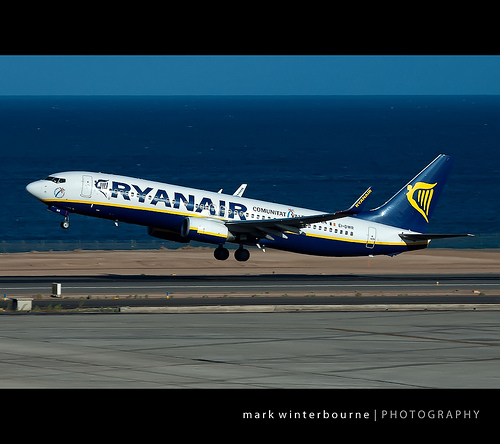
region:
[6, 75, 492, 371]
An airport scene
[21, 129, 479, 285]
This is a passenger jet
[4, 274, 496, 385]
This is a runway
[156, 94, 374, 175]
The ocean is in the background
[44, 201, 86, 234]
The plane's front landing gear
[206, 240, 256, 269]
These are the rear landing gears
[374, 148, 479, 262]
The jet's tail section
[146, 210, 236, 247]
The jet has two engines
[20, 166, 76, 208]
This is the plane's nose section.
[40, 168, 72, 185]
The cockpit windows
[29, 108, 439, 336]
the plane is white and blue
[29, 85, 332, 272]
the plane is white and blue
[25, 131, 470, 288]
a blue and white plane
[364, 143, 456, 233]
a blue stabilizer of plane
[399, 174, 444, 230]
yellow design on blue stabilizer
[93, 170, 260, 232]
side of plane says Ryanair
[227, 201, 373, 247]
right wing of plane is blue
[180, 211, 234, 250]
engine of plane is in front of wing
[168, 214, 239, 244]
engine is color white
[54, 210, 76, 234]
front wheel of plane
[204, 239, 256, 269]
back wheels of plane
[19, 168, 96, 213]
a door close to the cockpit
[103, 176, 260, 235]
the word Ryanair on the side of an airplane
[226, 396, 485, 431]
the photo credit in white text on black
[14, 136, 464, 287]
a large commercial aircraft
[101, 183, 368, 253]
a row of passenger windows alongside the plane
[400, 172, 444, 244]
a yellow angel symbol on the tail fin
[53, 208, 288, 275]
lowered landing gear beneath the plane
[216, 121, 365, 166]
deep blue ocean water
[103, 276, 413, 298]
a landing strip with a white lined center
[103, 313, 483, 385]
gray cement tiled ground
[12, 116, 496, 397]
a passenger airplane taking off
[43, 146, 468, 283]
The airplane is taking off.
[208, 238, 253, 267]
The wheels of the plane are down.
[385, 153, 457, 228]
The tail of the plane is gold and blue.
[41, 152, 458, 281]
The plane is white, blue and gold.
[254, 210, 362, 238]
The airplane has a lot of windows.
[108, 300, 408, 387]
The runway is paved.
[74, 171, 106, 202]
The door of the airplane by the cockpit.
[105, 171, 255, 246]
The writing on the plane is in blue.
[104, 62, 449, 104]
The sky is clear and blue.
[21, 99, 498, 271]
The runway is next to the ocean.